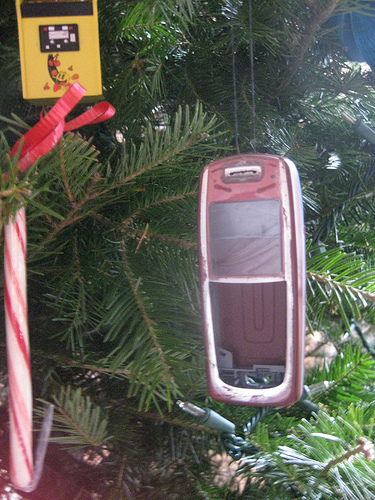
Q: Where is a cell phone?
A: Hanging from a tree.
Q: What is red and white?
A: Candy cane.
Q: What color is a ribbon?
A: Red.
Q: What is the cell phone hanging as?
A: An ornament.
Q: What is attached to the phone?
A: A string.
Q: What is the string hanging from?
A: Tree branch.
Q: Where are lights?
A: On the tree.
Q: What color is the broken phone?
A: Red.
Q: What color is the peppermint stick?
A: Red and white.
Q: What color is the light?
A: White.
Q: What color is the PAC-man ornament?
A: Yellow.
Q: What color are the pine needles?
A: Green.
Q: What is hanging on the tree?
A: Ornament.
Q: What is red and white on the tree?
A: Candy cane.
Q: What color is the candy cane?
A: Red and white.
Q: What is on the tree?
A: Electronic device.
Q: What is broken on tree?
A: Phone.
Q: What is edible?
A: Candy cane.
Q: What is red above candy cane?
A: Ribbon.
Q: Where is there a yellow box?
A: Above ribbon.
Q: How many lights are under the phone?
A: 1.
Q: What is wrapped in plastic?
A: Candy cane.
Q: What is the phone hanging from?
A: String on branch.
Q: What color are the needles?
A: Green.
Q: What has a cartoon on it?
A: Yellow box.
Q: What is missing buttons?
A: Phone.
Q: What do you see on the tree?
A: A toy.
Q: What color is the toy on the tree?
A: Maroon.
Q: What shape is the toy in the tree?
A: Rectangle.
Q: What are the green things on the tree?
A: Tree branches.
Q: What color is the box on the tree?
A: Yellow.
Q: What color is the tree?
A: Green.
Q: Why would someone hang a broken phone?
A: A joke.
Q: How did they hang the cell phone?
A: With string.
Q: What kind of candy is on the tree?
A: Candy cane.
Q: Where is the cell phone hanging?
A: On the tree.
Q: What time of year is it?
A: Christmas time.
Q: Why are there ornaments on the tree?
A: Holiday tradition.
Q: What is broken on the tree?
A: The cell phone.